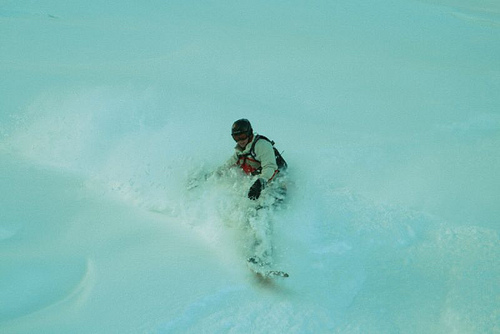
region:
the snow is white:
[352, 92, 434, 202]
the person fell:
[185, 75, 305, 292]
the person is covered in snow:
[207, 96, 292, 297]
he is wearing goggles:
[225, 128, 256, 146]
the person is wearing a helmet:
[227, 111, 254, 138]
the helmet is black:
[216, 115, 256, 135]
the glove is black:
[241, 177, 273, 205]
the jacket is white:
[255, 145, 283, 181]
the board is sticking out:
[247, 243, 314, 299]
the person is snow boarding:
[200, 107, 302, 284]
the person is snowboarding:
[168, 109, 315, 289]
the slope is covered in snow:
[16, 15, 484, 325]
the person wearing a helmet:
[211, 104, 307, 295]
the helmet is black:
[222, 115, 262, 149]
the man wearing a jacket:
[204, 138, 289, 216]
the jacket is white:
[203, 137, 298, 224]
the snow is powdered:
[169, 150, 260, 232]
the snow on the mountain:
[45, 102, 100, 203]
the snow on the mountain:
[24, 143, 178, 331]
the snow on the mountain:
[353, 29, 499, 157]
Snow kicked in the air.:
[164, 160, 325, 284]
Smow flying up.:
[108, 158, 264, 213]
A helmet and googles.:
[225, 109, 254, 151]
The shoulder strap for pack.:
[250, 132, 274, 161]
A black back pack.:
[271, 132, 295, 179]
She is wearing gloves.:
[244, 170, 270, 208]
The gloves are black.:
[243, 177, 268, 201]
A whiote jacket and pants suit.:
[213, 129, 297, 258]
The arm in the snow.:
[178, 135, 235, 202]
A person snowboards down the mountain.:
[184, 74, 315, 299]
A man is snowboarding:
[180, 103, 324, 308]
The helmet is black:
[213, 103, 268, 152]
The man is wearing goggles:
[223, 114, 262, 149]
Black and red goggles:
[226, 126, 264, 141]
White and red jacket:
[205, 110, 308, 213]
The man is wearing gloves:
[236, 173, 278, 201]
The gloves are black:
[235, 171, 268, 208]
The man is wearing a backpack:
[228, 111, 304, 192]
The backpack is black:
[246, 131, 299, 190]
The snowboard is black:
[234, 248, 314, 300]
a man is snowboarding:
[121, 93, 304, 298]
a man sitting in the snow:
[165, 35, 302, 329]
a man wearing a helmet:
[164, 95, 344, 282]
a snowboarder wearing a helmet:
[186, 114, 350, 317]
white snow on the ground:
[14, 149, 124, 292]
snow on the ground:
[29, 168, 113, 255]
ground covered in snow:
[22, 161, 170, 306]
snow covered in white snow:
[34, 209, 186, 319]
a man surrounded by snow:
[144, 98, 339, 330]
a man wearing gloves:
[139, 32, 354, 332]